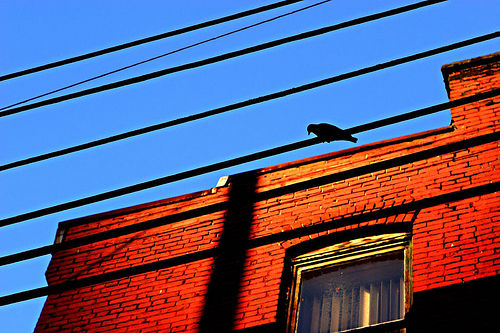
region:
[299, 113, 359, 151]
black bird on a wire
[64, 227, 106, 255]
red brick that is on building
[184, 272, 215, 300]
red brick that is on building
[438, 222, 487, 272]
red brick that is on building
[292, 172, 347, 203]
red brick that is on building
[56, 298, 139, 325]
red brick that is on building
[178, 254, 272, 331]
red brick that is on building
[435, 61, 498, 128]
red brick that is on building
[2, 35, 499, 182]
black power lines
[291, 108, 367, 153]
A bird sitting on a telephone wire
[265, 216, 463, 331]
A window on a brick building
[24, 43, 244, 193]
Black power lines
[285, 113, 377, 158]
A black bird on a wire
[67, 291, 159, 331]
A red brick wall on a building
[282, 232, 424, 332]
Brown blinds in a window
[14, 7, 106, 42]
A clear blue sky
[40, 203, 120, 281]
A corner of a brick building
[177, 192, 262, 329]
A black shadow on a building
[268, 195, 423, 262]
A brick arch above a window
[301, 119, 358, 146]
black bird on the wire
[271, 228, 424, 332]
window on the side of the building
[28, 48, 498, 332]
building is made of brick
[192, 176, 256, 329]
shadow on the side of the building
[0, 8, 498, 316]
thick black wires running alongside the building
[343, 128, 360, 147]
feathers on the tail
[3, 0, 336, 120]
thin wire between the thicker wires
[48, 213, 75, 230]
corner of the building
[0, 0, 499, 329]
bright blue sky with no clouds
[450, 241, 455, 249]
white mark on the building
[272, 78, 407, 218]
a bird on the power line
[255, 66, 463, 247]
a black bird on a power line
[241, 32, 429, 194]
a power line with a bird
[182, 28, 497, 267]
power line with a black bird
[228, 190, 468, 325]
a building with a window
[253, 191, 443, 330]
a window on a building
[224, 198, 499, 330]
a brick building with a window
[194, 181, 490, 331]
a window on a brick building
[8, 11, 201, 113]
a blue sky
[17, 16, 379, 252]
a sky that is blue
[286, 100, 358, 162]
this is a bird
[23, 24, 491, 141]
this is a line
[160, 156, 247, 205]
this is a line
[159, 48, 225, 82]
this is a line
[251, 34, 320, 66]
this is a line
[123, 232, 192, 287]
these are bricks on a wall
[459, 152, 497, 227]
these are bricks on a wall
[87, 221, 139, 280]
these are bricks on a wall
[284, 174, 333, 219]
these are bricks on a wall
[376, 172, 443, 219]
these are bricks on a wall